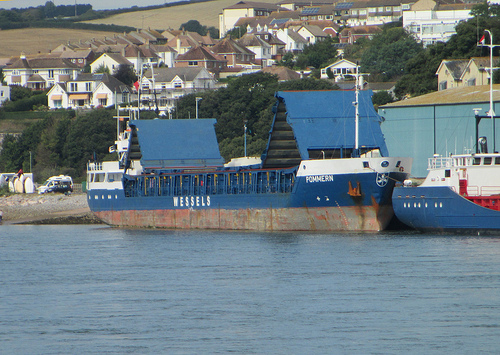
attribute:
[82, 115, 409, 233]
cargo ship — blue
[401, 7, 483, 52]
building — large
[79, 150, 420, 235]
ship — blue and white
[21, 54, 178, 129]
building — large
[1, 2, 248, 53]
hill — brown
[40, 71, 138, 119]
house — multiple stories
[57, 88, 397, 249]
ship — rusted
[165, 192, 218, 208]
writing — white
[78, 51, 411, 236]
boat — white, red, blue, large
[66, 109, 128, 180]
tree — green, large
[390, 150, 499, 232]
ship — blue and white and red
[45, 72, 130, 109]
house — white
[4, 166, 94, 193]
cars — parked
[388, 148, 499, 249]
boat — red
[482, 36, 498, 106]
pole — white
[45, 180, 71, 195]
sedan — black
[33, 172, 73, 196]
van — white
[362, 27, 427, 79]
tree — green, large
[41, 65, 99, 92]
overhangs — brown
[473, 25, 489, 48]
flag — red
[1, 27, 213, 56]
roofs — grey, brown